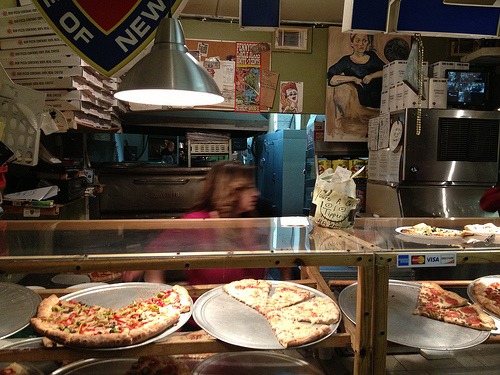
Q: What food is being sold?
A: Pizza.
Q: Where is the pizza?
A: On the pans.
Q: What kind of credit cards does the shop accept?
A: Visa, Mastercard, American Express, Discover.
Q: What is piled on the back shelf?
A: Empty pizza boxes.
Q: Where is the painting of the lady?
A: On the wall.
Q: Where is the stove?
A: By the wall.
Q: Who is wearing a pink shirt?
A: The woman behind the counter.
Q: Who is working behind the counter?
A: A woman in a pink shirt.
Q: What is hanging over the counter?
A: A silver light.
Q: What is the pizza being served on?
A: A pan.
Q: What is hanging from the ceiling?
A: A lamp.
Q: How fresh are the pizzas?
A: Very fresh.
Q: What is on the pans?
A: PIzza.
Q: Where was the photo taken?
A: Pizza place.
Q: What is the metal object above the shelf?
A: Light.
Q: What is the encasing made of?
A: Glass.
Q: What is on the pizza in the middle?
A: Cheese.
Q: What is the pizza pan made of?
A: Metal.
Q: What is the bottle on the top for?
A: Tips.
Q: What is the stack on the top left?
A: Boxes.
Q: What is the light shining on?
A: PIzza.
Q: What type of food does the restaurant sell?
A: Pizza.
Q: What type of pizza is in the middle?
A: Cheese.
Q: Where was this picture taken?
A: Pizza restaurant.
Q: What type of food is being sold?
A: Pizza.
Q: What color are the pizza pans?
A: Silver.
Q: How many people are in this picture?
A: 1.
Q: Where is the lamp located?
A: Over pizzas.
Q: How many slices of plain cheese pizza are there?
A: 4.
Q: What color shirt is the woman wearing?
A: Pink.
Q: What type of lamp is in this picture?
A: Heat lamp.